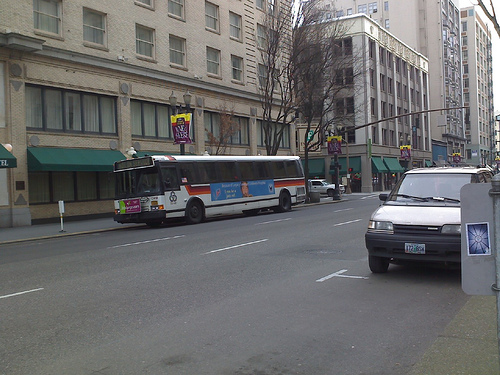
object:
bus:
[111, 150, 310, 227]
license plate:
[404, 242, 426, 252]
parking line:
[313, 262, 369, 289]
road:
[0, 192, 500, 374]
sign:
[209, 180, 278, 201]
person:
[240, 182, 256, 197]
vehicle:
[362, 161, 496, 281]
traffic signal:
[462, 104, 473, 126]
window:
[204, 58, 223, 76]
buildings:
[0, 0, 305, 232]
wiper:
[426, 194, 460, 205]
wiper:
[387, 190, 429, 203]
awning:
[31, 147, 129, 176]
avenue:
[0, 0, 500, 371]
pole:
[335, 103, 475, 139]